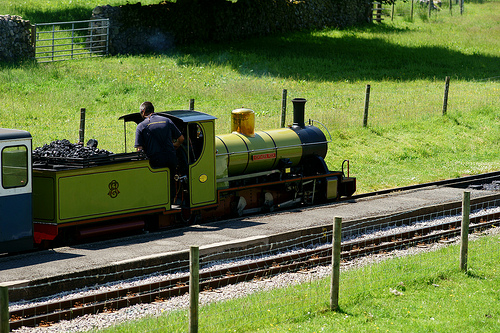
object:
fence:
[0, 199, 499, 332]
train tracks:
[0, 193, 499, 327]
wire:
[190, 229, 335, 261]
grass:
[0, 0, 499, 198]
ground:
[0, 0, 498, 332]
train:
[0, 90, 358, 257]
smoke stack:
[290, 97, 307, 126]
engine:
[121, 89, 358, 227]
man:
[133, 102, 185, 206]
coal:
[83, 137, 98, 150]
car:
[0, 126, 36, 254]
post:
[360, 82, 372, 129]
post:
[327, 215, 343, 311]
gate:
[31, 18, 110, 65]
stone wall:
[91, 0, 376, 56]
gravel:
[9, 206, 499, 332]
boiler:
[228, 107, 256, 136]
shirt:
[134, 115, 185, 156]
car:
[27, 107, 169, 250]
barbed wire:
[0, 201, 499, 314]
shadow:
[153, 34, 499, 83]